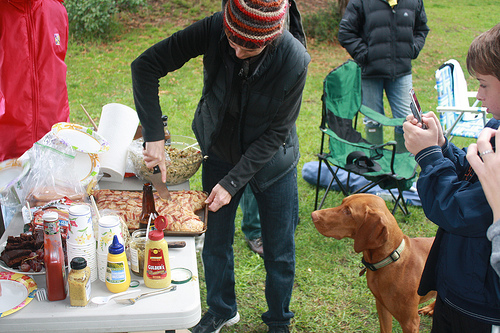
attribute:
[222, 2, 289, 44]
hat — knit, striped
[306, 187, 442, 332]
dog — brown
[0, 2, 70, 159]
jacket — red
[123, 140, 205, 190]
bowl — large, see through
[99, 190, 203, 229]
pizza — square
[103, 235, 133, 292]
bottle — yellow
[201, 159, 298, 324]
denim pants — dark blue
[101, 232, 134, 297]
bottle — yellow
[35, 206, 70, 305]
ketchup — red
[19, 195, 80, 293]
ketchup — Hunt's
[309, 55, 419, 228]
chair — green, canvas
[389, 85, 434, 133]
cellphone — taking photo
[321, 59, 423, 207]
chair — green, folding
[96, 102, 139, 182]
paper towels — white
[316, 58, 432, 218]
chair — green, outdoor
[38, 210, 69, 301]
bottle — tall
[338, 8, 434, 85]
winter jacket — black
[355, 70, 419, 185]
pants — light blue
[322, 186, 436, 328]
dog — brown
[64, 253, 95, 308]
mustard — small jar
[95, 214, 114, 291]
paper cups — stacked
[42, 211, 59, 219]
lid — white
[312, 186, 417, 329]
dog — brown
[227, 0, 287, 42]
beanie — red, white, brown, gray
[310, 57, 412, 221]
camp chair — black, green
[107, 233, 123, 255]
lid — blue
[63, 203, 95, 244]
cup — paper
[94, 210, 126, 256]
cup — paper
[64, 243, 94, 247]
cup — paper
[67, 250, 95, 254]
cup — paper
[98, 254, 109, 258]
cup — paper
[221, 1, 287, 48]
hat — colorful, wool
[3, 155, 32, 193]
plate — paper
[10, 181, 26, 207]
plate — paper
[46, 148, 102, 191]
plate — paper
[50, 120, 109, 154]
plate — paper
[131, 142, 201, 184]
salad — mixed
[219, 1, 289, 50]
cap — wool, striped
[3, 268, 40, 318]
rim — colorful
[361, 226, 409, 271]
neck — dog's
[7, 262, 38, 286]
border — bright colored